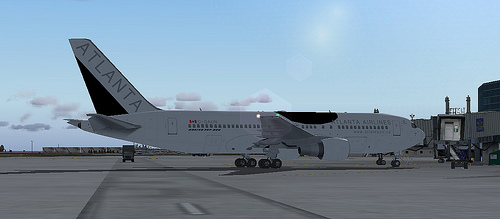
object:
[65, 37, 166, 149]
tail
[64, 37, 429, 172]
plane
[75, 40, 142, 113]
lettering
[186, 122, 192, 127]
window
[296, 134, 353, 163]
engine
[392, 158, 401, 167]
wheel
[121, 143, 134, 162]
truck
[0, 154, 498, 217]
tarmac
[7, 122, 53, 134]
cloud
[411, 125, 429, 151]
nose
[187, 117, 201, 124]
flag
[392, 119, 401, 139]
door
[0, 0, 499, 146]
sky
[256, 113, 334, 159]
wing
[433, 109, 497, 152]
dock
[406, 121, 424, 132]
cockpit